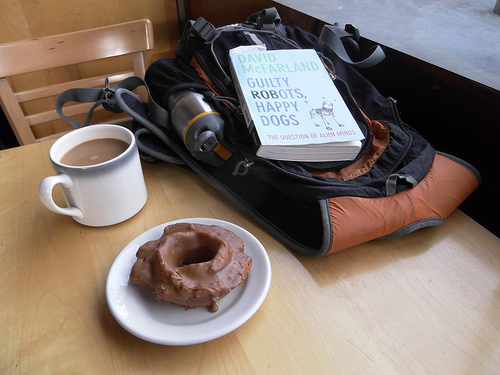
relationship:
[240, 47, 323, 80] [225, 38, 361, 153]
author of book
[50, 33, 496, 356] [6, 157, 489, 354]
backpack on table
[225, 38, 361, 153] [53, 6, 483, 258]
book on backpack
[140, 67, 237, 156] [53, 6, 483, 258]
bottle in backpack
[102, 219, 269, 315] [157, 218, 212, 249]
donut with frosting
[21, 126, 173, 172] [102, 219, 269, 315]
coffee and donut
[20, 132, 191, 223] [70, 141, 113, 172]
cup has tea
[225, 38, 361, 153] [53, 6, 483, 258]
book in backpack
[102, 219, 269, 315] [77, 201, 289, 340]
donut on plate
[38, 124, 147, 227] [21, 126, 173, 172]
cup of coffee